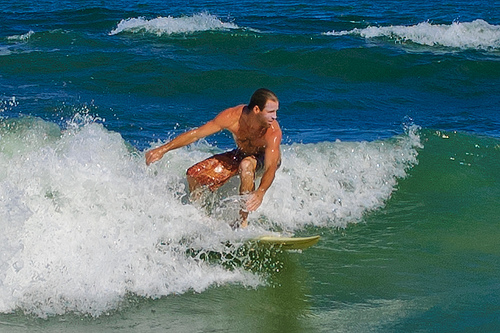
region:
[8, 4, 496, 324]
Man surfing in the ocean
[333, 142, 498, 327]
Green ocean water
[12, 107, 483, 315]
Small wave crashing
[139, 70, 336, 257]
Man riding on a white surfboard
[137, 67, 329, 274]
Man wearing orange board shorts without a shirt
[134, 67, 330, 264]
Man with brown hair surfing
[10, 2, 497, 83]
Blue and green ocean water and waves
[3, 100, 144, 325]
White water splash from a breaking wave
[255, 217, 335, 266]
Nose of the surfboard coming out of the water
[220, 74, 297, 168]
Man with hair on his chest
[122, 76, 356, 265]
The man is surfing.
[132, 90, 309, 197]
The man is shirtless.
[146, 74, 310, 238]
The man is wet.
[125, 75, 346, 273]
The man rides a wave.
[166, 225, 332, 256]
The surfboard is partially hidden.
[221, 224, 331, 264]
The surfboard is yellow.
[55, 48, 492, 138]
The water is deep blue.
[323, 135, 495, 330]
The water is green.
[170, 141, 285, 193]
The man wears shorts.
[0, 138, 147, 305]
The churned up water is white.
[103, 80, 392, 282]
Surfer on the wave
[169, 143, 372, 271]
Surfer on the surfboard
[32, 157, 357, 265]
White water on the wave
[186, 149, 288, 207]
Swimmer shorts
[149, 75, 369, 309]
Surfer on the water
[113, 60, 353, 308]
Riding the waves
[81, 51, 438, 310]
Surfer in the ocean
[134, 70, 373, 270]
Riding the ocean waves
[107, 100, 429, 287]
Nice waves for surfing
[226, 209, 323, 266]
Yellow surfboard in the ocean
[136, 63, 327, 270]
Surfer is crouch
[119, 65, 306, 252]
Surfer do not wear top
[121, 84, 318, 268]
Surfer stand in a surfboard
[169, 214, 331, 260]
Surfboard is white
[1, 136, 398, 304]
Wave is white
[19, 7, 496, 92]
Water is choppy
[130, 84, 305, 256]
Surfer has right hand extended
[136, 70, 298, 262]
Surfer has short hair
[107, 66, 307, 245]
Surfer face to the right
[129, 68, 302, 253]
Left hand of surfer touch his left leg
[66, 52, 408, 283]
person surfing the nice waves.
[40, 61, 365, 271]
person surfing great waves in the ocean.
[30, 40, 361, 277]
person surfing awesome waves in the ocean.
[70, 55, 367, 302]
person surfing great waves in daytime.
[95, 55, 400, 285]
man surfing some really great waves.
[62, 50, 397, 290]
man surfing some really awesome waves.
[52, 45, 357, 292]
man surfing some really beautiful waves.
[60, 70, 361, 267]
man surfing some really good waves.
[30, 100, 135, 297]
some beautiful waves in the ocean.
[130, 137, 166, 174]
right hand in some water.